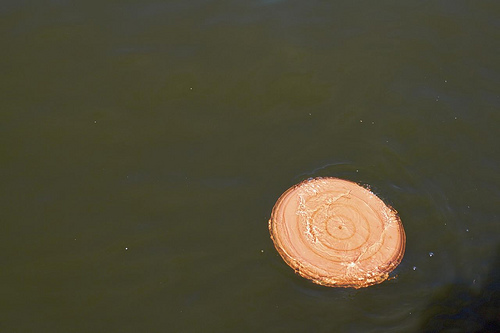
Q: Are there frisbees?
A: Yes, there is a frisbee.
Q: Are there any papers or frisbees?
A: Yes, there is a frisbee.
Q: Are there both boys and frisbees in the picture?
A: No, there is a frisbee but no boys.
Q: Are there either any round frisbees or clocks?
A: Yes, there is a round frisbee.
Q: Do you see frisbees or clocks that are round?
A: Yes, the frisbee is round.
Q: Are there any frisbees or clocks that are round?
A: Yes, the frisbee is round.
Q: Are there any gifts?
A: No, there are no gifts.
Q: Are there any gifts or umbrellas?
A: No, there are no gifts or umbrellas.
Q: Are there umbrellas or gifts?
A: No, there are no gifts or umbrellas.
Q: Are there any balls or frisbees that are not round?
A: No, there is a frisbee but it is round.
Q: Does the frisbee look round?
A: Yes, the frisbee is round.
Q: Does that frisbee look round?
A: Yes, the frisbee is round.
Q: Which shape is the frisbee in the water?
A: The frisbee is round.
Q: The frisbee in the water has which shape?
A: The frisbee is round.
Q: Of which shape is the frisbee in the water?
A: The frisbee is round.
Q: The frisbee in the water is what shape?
A: The frisbee is round.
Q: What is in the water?
A: The frisbee is in the water.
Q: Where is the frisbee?
A: The frisbee is in the water.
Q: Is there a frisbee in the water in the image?
A: Yes, there is a frisbee in the water.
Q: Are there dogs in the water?
A: No, there is a frisbee in the water.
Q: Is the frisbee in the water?
A: Yes, the frisbee is in the water.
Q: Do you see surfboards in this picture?
A: No, there are no surfboards.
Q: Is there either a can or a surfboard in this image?
A: No, there are no surfboards or cans.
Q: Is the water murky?
A: Yes, the water is murky.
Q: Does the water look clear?
A: No, the water is murky.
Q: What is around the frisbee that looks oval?
A: The water is around the frisbee.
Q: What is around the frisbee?
A: The water is around the frisbee.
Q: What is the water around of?
A: The water is around the frisbee.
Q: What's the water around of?
A: The water is around the frisbee.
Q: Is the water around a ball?
A: No, the water is around the frisbee.